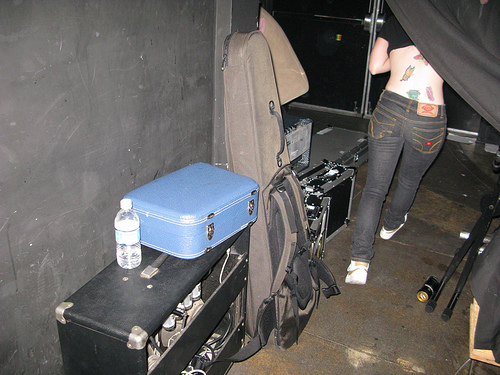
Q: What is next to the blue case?
A: Water bottle.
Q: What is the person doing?
A: Walking away.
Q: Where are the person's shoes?
A: On their feet.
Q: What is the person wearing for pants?
A: Jeans.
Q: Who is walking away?
A: Girl.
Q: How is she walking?
A: With legs.